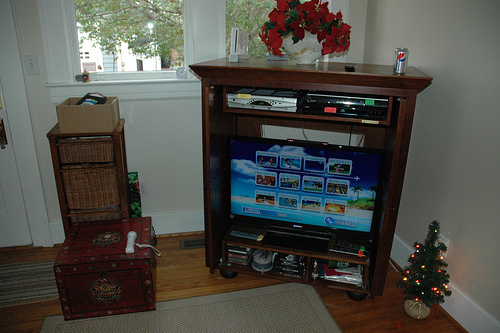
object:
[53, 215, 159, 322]
box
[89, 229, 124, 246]
design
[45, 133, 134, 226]
shelf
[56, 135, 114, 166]
baskets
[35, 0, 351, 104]
window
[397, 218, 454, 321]
tree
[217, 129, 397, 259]
tv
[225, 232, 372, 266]
shelf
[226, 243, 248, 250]
cds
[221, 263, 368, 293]
shelf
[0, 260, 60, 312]
mat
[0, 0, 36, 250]
door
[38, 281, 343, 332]
rug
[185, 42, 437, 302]
stand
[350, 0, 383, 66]
corner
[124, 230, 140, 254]
remote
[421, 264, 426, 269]
lights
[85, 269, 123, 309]
design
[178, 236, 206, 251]
vent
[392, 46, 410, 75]
can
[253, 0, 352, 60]
poinsettia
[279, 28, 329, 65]
vase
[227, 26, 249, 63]
wii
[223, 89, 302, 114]
box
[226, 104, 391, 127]
shelf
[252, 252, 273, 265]
cds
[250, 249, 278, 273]
holder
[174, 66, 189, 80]
clock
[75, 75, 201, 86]
sill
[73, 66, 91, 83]
decoration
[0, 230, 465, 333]
floor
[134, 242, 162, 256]
strap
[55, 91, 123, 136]
cardboard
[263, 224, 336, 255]
stand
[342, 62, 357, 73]
remote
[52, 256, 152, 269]
border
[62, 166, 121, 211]
basket